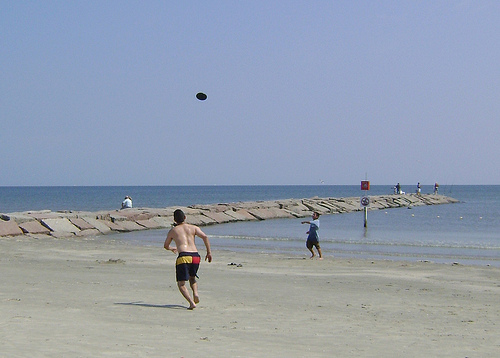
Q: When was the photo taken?
A: Daytime.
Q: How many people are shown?
A: Six.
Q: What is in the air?
A: Frisbee.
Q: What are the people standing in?
A: Sand.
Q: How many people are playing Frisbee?
A: Two.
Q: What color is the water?
A: Blue.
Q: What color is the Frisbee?
A: Black.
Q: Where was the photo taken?
A: At the beach.